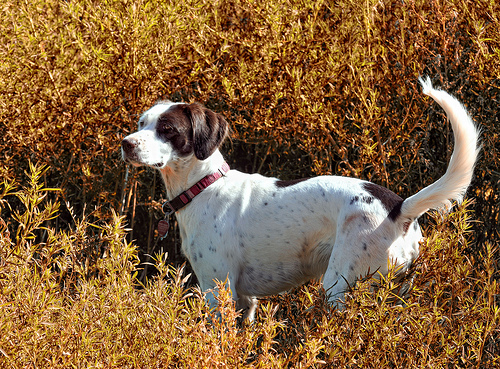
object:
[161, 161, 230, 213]
collar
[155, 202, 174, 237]
tags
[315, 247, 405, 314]
legs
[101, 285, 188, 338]
leaves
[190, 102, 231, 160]
ear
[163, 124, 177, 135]
eye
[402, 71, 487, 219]
tail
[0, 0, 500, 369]
grass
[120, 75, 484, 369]
dog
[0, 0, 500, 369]
field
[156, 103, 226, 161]
spot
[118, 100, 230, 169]
head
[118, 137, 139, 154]
nose